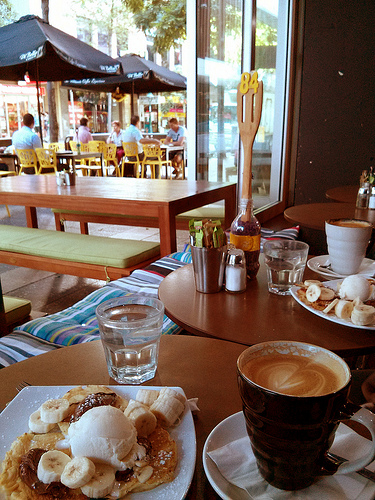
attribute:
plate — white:
[0, 384, 196, 498]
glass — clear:
[90, 293, 169, 388]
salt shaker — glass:
[226, 248, 245, 294]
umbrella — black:
[1, 14, 124, 79]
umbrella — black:
[61, 52, 186, 90]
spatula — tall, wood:
[217, 87, 281, 212]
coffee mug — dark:
[231, 342, 374, 486]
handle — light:
[322, 405, 372, 478]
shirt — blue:
[9, 123, 43, 150]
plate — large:
[2, 330, 252, 425]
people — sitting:
[10, 106, 194, 159]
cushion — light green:
[34, 220, 145, 272]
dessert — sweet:
[2, 383, 190, 498]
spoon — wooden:
[234, 71, 264, 219]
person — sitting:
[160, 117, 185, 179]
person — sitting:
[122, 115, 160, 176]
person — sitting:
[107, 119, 125, 174]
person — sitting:
[75, 117, 92, 176]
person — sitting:
[12, 113, 69, 172]